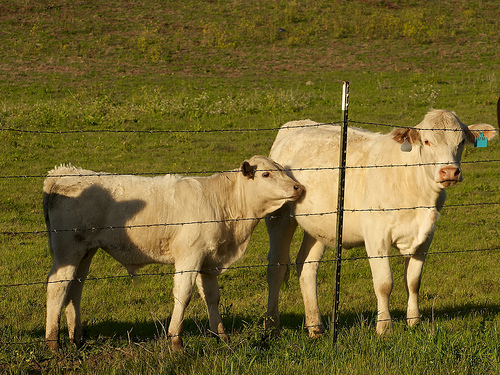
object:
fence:
[2, 78, 499, 340]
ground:
[0, 0, 500, 375]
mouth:
[436, 177, 463, 187]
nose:
[440, 166, 462, 181]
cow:
[40, 154, 302, 353]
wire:
[0, 122, 346, 132]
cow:
[265, 106, 496, 338]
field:
[1, 0, 497, 372]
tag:
[475, 138, 489, 149]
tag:
[399, 137, 413, 152]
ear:
[390, 126, 418, 145]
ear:
[239, 160, 254, 177]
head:
[392, 107, 497, 190]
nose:
[291, 183, 305, 192]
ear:
[463, 122, 495, 144]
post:
[330, 76, 352, 348]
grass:
[0, 0, 499, 374]